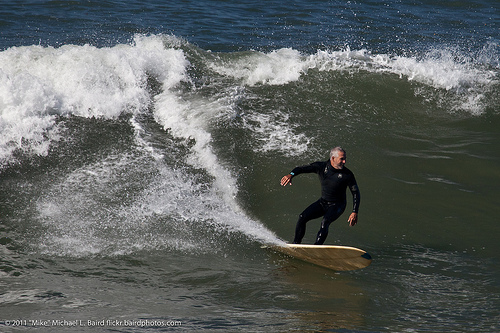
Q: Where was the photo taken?
A: It was taken at the ocean.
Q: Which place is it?
A: It is an ocean.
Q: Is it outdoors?
A: Yes, it is outdoors.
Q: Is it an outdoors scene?
A: Yes, it is outdoors.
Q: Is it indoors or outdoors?
A: It is outdoors.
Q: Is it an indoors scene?
A: No, it is outdoors.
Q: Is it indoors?
A: No, it is outdoors.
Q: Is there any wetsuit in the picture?
A: Yes, there is a wetsuit.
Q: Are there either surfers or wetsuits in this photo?
A: Yes, there is a wetsuit.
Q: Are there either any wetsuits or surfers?
A: Yes, there is a wetsuit.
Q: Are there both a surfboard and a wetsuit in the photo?
A: Yes, there are both a wetsuit and a surfboard.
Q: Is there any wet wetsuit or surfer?
A: Yes, there is a wet wetsuit.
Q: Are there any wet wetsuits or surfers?
A: Yes, there is a wet wetsuit.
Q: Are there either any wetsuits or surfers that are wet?
A: Yes, the wetsuit is wet.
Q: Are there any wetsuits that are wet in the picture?
A: Yes, there is a wet wetsuit.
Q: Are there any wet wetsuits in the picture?
A: Yes, there is a wet wetsuit.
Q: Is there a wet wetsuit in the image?
A: Yes, there is a wet wetsuit.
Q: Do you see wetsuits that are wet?
A: Yes, there is a wetsuit that is wet.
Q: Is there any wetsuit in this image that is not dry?
A: Yes, there is a wet wetsuit.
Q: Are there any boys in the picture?
A: No, there are no boys.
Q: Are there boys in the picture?
A: No, there are no boys.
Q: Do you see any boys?
A: No, there are no boys.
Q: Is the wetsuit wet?
A: Yes, the wetsuit is wet.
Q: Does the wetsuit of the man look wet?
A: Yes, the wetsuit is wet.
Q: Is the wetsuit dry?
A: No, the wetsuit is wet.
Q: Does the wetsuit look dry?
A: No, the wetsuit is wet.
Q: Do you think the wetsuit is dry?
A: No, the wetsuit is wet.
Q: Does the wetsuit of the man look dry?
A: No, the wet suit is wet.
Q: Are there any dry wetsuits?
A: No, there is a wetsuit but it is wet.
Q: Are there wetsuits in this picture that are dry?
A: No, there is a wetsuit but it is wet.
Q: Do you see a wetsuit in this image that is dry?
A: No, there is a wetsuit but it is wet.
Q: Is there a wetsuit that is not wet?
A: No, there is a wetsuit but it is wet.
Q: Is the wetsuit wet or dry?
A: The wetsuit is wet.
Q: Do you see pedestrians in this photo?
A: No, there are no pedestrians.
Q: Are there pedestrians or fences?
A: No, there are no pedestrians or fences.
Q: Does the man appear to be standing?
A: Yes, the man is standing.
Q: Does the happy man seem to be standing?
A: Yes, the man is standing.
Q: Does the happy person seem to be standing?
A: Yes, the man is standing.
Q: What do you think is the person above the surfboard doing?
A: The man is standing.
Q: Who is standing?
A: The man is standing.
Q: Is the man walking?
A: No, the man is standing.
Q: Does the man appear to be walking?
A: No, the man is standing.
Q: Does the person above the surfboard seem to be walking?
A: No, the man is standing.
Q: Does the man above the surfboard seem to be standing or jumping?
A: The man is standing.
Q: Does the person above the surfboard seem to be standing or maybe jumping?
A: The man is standing.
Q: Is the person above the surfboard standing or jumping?
A: The man is standing.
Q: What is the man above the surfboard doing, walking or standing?
A: The man is standing.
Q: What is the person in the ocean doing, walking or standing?
A: The man is standing.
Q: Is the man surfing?
A: Yes, the man is surfing.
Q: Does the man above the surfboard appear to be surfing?
A: Yes, the man is surfing.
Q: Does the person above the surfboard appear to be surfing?
A: Yes, the man is surfing.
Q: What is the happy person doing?
A: The man is surfing.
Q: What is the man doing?
A: The man is surfing.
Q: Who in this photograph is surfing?
A: The man is surfing.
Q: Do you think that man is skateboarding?
A: No, the man is surfing.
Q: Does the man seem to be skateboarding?
A: No, the man is surfing.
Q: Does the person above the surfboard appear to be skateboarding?
A: No, the man is surfing.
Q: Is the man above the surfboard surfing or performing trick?
A: The man is surfing.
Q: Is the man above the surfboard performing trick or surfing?
A: The man is surfing.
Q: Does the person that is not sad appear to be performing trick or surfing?
A: The man is surfing.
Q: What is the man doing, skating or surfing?
A: The man is surfing.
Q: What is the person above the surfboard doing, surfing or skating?
A: The man is surfing.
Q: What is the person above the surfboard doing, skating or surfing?
A: The man is surfing.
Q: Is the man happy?
A: Yes, the man is happy.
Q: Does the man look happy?
A: Yes, the man is happy.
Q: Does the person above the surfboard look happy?
A: Yes, the man is happy.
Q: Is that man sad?
A: No, the man is happy.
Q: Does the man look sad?
A: No, the man is happy.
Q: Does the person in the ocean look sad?
A: No, the man is happy.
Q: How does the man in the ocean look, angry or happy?
A: The man is happy.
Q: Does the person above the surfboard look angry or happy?
A: The man is happy.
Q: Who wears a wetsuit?
A: The man wears a wetsuit.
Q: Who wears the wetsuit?
A: The man wears a wetsuit.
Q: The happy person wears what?
A: The man wears a wetsuit.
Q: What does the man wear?
A: The man wears a wetsuit.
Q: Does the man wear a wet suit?
A: Yes, the man wears a wet suit.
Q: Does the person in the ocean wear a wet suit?
A: Yes, the man wears a wet suit.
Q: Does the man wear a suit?
A: No, the man wears a wet suit.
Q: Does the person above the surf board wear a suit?
A: No, the man wears a wet suit.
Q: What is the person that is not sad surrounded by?
A: The man is surrounded by the water.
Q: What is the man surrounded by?
A: The man is surrounded by the water.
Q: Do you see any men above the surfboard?
A: Yes, there is a man above the surfboard.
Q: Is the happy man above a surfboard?
A: Yes, the man is above a surfboard.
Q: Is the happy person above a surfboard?
A: Yes, the man is above a surfboard.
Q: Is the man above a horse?
A: No, the man is above a surfboard.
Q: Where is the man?
A: The man is in the ocean.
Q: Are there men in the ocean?
A: Yes, there is a man in the ocean.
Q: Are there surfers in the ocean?
A: No, there is a man in the ocean.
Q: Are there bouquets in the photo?
A: No, there are no bouquets.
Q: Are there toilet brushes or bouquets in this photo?
A: No, there are no bouquets or toilet brushes.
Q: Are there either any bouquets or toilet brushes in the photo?
A: No, there are no bouquets or toilet brushes.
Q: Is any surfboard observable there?
A: Yes, there is a surfboard.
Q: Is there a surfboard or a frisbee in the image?
A: Yes, there is a surfboard.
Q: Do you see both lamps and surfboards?
A: No, there is a surfboard but no lamps.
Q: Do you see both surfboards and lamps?
A: No, there is a surfboard but no lamps.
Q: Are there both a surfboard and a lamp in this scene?
A: No, there is a surfboard but no lamps.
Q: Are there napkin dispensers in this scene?
A: No, there are no napkin dispensers.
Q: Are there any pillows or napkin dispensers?
A: No, there are no napkin dispensers or pillows.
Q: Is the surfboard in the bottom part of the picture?
A: Yes, the surfboard is in the bottom of the image.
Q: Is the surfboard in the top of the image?
A: No, the surfboard is in the bottom of the image.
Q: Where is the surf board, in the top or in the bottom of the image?
A: The surf board is in the bottom of the image.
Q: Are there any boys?
A: No, there are no boys.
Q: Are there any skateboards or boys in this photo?
A: No, there are no boys or skateboards.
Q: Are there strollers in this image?
A: No, there are no strollers.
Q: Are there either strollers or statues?
A: No, there are no strollers or statues.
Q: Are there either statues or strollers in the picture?
A: No, there are no strollers or statues.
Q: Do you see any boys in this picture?
A: No, there are no boys.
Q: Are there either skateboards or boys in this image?
A: No, there are no boys or skateboards.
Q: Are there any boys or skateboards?
A: No, there are no boys or skateboards.